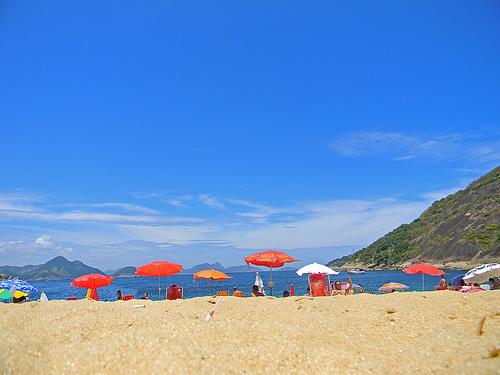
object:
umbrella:
[136, 260, 182, 301]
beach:
[0, 288, 498, 374]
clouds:
[0, 189, 452, 268]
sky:
[0, 7, 500, 273]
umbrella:
[193, 268, 234, 296]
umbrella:
[295, 262, 341, 277]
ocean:
[0, 269, 492, 304]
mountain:
[0, 255, 108, 282]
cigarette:
[205, 297, 222, 321]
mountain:
[320, 161, 499, 273]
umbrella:
[462, 263, 499, 286]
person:
[165, 284, 181, 300]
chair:
[167, 284, 183, 300]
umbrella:
[378, 281, 410, 293]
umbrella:
[243, 249, 300, 296]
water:
[1, 269, 495, 303]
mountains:
[0, 256, 344, 283]